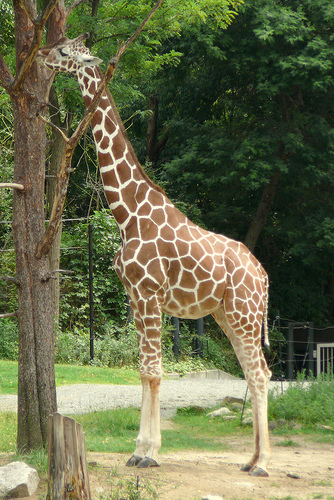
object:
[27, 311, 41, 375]
bark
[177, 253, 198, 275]
spots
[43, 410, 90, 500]
stump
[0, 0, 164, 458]
tree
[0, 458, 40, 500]
rock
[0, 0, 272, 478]
giraffe eating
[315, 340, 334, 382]
fence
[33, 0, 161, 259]
branch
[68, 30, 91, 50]
ossicone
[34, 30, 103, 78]
head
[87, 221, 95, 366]
pole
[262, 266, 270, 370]
tail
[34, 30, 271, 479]
giraffe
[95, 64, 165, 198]
mane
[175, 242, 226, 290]
fur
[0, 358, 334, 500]
ground